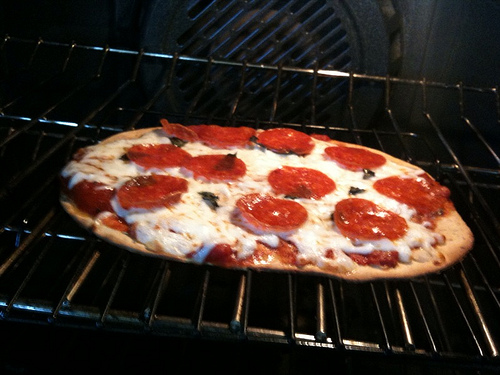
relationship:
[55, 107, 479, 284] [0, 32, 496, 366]
pizza sitting on rack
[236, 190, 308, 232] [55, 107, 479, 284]
pepperoni on top of pizza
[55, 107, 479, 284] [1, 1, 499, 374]
pizza inside oven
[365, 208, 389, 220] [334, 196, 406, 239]
glare on pepperoni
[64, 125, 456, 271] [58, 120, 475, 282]
cheese on crust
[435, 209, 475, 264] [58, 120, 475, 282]
hunk of crust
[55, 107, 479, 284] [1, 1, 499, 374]
pizza in oven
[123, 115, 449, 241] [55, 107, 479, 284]
pepperoni on pizza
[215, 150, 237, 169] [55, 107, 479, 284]
anchovies on pizza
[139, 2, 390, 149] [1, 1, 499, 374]
heater on oven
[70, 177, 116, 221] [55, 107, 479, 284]
sauce on pizza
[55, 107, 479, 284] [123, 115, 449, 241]
pizza has pepperoni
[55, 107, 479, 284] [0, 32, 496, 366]
pizza on oven grill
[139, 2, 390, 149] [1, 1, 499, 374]
vent inside oven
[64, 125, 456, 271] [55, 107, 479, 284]
cheese on pizza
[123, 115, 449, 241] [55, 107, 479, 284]
pepperoni slices on pizza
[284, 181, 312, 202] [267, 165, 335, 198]
leaf behind pepperoni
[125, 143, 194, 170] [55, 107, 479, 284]
slice on pizza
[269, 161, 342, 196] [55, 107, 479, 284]
pepperoni on pizza